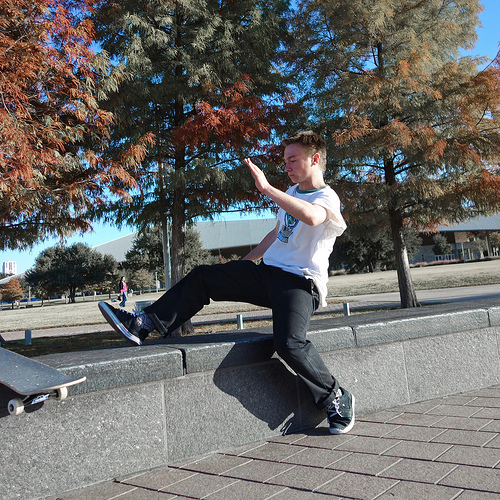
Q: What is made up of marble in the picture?
A: The short wall.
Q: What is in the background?
A: Building.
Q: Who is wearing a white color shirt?
A: A man.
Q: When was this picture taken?
A: On a sunny day.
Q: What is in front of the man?
A: A skateboard.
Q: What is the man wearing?
A: A black jeans.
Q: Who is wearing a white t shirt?
A: The boy.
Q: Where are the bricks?
A: On the walk.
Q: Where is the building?
A: Background.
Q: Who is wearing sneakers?
A: The boy.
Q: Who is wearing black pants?
A: The boy.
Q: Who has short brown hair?
A: The man.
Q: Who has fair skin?
A: The man.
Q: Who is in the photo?
A: A man.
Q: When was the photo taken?
A: During the day.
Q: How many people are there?
A: One.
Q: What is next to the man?
A: Trees.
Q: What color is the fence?
A: Grey.